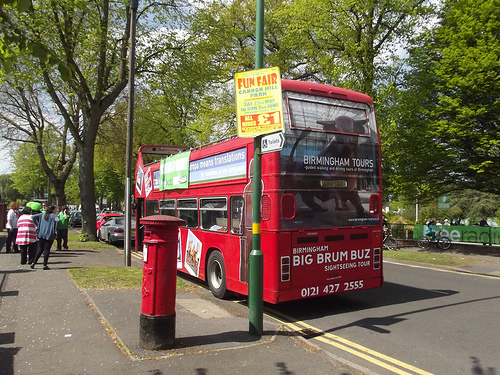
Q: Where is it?
A: This is at the street.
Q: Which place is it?
A: It is a street.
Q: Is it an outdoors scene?
A: Yes, it is outdoors.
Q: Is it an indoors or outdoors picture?
A: It is outdoors.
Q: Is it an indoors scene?
A: No, it is outdoors.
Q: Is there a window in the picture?
A: Yes, there is a window.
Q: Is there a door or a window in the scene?
A: Yes, there is a window.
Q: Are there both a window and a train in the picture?
A: No, there is a window but no trains.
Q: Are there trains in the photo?
A: No, there are no trains.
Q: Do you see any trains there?
A: No, there are no trains.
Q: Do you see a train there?
A: No, there are no trains.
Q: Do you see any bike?
A: Yes, there is a bike.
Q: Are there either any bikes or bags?
A: Yes, there is a bike.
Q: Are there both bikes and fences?
A: No, there is a bike but no fences.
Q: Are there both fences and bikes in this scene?
A: No, there is a bike but no fences.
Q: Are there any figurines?
A: No, there are no figurines.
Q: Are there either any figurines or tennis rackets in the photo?
A: No, there are no figurines or tennis rackets.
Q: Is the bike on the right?
A: Yes, the bike is on the right of the image.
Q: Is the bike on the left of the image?
A: No, the bike is on the right of the image.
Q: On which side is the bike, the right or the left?
A: The bike is on the right of the image.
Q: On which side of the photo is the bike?
A: The bike is on the right of the image.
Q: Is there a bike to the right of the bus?
A: Yes, there is a bike to the right of the bus.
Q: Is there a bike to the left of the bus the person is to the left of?
A: No, the bike is to the right of the bus.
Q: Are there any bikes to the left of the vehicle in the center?
A: No, the bike is to the right of the bus.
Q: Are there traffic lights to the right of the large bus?
A: No, there is a bike to the right of the bus.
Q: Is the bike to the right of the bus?
A: Yes, the bike is to the right of the bus.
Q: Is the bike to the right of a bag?
A: No, the bike is to the right of the bus.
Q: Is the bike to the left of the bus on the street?
A: No, the bike is to the right of the bus.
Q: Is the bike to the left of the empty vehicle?
A: No, the bike is to the right of the bus.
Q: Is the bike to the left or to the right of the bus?
A: The bike is to the right of the bus.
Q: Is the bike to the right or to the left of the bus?
A: The bike is to the right of the bus.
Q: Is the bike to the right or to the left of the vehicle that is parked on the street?
A: The bike is to the right of the bus.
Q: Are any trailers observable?
A: No, there are no trailers.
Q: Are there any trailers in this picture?
A: No, there are no trailers.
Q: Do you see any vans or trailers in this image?
A: No, there are no trailers or vans.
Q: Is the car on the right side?
A: No, the car is on the left of the image.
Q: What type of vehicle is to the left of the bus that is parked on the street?
A: The vehicle is a car.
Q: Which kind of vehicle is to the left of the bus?
A: The vehicle is a car.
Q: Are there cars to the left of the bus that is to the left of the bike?
A: Yes, there is a car to the left of the bus.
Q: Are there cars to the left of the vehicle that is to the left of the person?
A: Yes, there is a car to the left of the bus.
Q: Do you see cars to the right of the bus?
A: No, the car is to the left of the bus.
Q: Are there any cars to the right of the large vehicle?
A: No, the car is to the left of the bus.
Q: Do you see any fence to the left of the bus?
A: No, there is a car to the left of the bus.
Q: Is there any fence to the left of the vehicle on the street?
A: No, there is a car to the left of the bus.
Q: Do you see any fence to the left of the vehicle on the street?
A: No, there is a car to the left of the bus.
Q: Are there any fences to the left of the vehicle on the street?
A: No, there is a car to the left of the bus.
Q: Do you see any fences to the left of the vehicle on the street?
A: No, there is a car to the left of the bus.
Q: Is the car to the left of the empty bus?
A: Yes, the car is to the left of the bus.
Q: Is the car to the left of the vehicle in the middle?
A: Yes, the car is to the left of the bus.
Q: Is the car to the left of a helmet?
A: No, the car is to the left of the bus.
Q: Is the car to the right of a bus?
A: No, the car is to the left of a bus.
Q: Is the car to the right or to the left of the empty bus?
A: The car is to the left of the bus.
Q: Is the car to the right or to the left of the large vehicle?
A: The car is to the left of the bus.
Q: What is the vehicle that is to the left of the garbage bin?
A: The vehicle is a car.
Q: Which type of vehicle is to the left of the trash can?
A: The vehicle is a car.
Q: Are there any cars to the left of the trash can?
A: Yes, there is a car to the left of the trash can.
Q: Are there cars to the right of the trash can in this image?
A: No, the car is to the left of the trash can.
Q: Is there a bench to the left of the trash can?
A: No, there is a car to the left of the trash can.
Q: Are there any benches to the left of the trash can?
A: No, there is a car to the left of the trash can.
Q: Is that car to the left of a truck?
A: No, the car is to the left of a trash can.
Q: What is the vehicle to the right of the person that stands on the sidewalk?
A: The vehicle is a car.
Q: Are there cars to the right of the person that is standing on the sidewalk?
A: Yes, there is a car to the right of the person.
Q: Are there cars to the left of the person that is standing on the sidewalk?
A: No, the car is to the right of the person.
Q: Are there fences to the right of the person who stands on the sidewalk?
A: No, there is a car to the right of the person.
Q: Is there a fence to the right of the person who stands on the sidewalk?
A: No, there is a car to the right of the person.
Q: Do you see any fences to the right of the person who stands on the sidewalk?
A: No, there is a car to the right of the person.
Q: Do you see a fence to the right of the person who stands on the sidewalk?
A: No, there is a car to the right of the person.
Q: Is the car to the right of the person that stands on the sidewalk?
A: Yes, the car is to the right of the person.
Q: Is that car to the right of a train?
A: No, the car is to the right of the person.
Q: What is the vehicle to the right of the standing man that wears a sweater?
A: The vehicle is a car.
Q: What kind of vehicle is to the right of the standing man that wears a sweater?
A: The vehicle is a car.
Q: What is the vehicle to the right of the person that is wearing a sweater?
A: The vehicle is a car.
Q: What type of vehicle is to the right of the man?
A: The vehicle is a car.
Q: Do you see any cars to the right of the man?
A: Yes, there is a car to the right of the man.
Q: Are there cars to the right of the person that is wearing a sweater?
A: Yes, there is a car to the right of the man.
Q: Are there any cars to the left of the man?
A: No, the car is to the right of the man.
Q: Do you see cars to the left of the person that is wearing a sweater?
A: No, the car is to the right of the man.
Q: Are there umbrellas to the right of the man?
A: No, there is a car to the right of the man.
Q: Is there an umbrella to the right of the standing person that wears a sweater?
A: No, there is a car to the right of the man.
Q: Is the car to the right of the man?
A: Yes, the car is to the right of the man.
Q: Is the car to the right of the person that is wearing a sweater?
A: Yes, the car is to the right of the man.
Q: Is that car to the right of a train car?
A: No, the car is to the right of the man.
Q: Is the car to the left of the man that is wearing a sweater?
A: No, the car is to the right of the man.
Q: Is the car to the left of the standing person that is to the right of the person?
A: No, the car is to the right of the man.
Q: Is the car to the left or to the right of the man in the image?
A: The car is to the right of the man.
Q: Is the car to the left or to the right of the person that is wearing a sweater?
A: The car is to the right of the man.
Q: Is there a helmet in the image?
A: No, there are no helmets.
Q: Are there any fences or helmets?
A: No, there are no helmets or fences.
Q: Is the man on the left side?
A: Yes, the man is on the left of the image.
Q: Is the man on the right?
A: No, the man is on the left of the image.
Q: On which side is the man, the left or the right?
A: The man is on the left of the image.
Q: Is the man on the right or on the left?
A: The man is on the left of the image.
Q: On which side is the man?
A: The man is on the left of the image.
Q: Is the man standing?
A: Yes, the man is standing.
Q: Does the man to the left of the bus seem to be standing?
A: Yes, the man is standing.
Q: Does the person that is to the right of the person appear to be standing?
A: Yes, the man is standing.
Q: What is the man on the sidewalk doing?
A: The man is standing.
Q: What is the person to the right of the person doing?
A: The man is standing.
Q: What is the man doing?
A: The man is standing.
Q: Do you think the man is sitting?
A: No, the man is standing.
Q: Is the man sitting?
A: No, the man is standing.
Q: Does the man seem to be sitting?
A: No, the man is standing.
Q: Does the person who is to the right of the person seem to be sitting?
A: No, the man is standing.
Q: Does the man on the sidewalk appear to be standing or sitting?
A: The man is standing.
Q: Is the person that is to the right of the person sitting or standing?
A: The man is standing.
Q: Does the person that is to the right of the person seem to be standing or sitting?
A: The man is standing.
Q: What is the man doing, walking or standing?
A: The man is standing.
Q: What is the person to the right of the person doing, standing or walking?
A: The man is standing.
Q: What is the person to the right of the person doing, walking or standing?
A: The man is standing.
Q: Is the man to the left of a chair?
A: No, the man is to the left of the trash bin.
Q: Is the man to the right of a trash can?
A: No, the man is to the left of a trash can.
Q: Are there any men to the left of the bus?
A: Yes, there is a man to the left of the bus.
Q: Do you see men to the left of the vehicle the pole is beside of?
A: Yes, there is a man to the left of the bus.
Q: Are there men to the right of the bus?
A: No, the man is to the left of the bus.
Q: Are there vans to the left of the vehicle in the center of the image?
A: No, there is a man to the left of the bus.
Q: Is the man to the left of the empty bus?
A: Yes, the man is to the left of the bus.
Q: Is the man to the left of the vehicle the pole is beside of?
A: Yes, the man is to the left of the bus.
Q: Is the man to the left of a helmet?
A: No, the man is to the left of the bus.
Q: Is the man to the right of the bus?
A: No, the man is to the left of the bus.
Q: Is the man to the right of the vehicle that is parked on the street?
A: No, the man is to the left of the bus.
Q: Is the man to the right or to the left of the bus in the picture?
A: The man is to the left of the bus.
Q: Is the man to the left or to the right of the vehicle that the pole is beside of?
A: The man is to the left of the bus.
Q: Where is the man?
A: The man is on the sidewalk.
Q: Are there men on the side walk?
A: Yes, there is a man on the side walk.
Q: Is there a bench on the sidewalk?
A: No, there is a man on the sidewalk.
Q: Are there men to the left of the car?
A: Yes, there is a man to the left of the car.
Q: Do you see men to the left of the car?
A: Yes, there is a man to the left of the car.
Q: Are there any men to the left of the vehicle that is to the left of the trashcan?
A: Yes, there is a man to the left of the car.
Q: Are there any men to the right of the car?
A: No, the man is to the left of the car.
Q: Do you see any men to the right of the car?
A: No, the man is to the left of the car.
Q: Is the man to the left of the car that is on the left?
A: Yes, the man is to the left of the car.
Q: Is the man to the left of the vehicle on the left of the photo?
A: Yes, the man is to the left of the car.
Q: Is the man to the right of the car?
A: No, the man is to the left of the car.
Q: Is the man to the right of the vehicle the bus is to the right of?
A: No, the man is to the left of the car.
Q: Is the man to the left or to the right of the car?
A: The man is to the left of the car.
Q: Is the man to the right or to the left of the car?
A: The man is to the left of the car.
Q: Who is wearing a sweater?
A: The man is wearing a sweater.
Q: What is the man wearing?
A: The man is wearing a sweater.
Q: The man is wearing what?
A: The man is wearing a sweater.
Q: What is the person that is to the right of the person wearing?
A: The man is wearing a sweater.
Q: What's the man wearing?
A: The man is wearing a sweater.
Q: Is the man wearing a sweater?
A: Yes, the man is wearing a sweater.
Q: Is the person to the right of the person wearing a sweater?
A: Yes, the man is wearing a sweater.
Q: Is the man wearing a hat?
A: No, the man is wearing a sweater.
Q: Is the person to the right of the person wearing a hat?
A: No, the man is wearing a sweater.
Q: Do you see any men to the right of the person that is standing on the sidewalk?
A: Yes, there is a man to the right of the person.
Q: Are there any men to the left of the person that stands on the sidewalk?
A: No, the man is to the right of the person.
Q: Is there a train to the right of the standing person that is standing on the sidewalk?
A: No, there is a man to the right of the person.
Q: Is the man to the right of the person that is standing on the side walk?
A: Yes, the man is to the right of the person.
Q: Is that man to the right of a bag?
A: No, the man is to the right of the person.